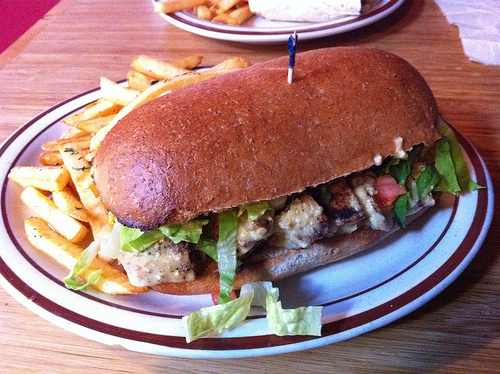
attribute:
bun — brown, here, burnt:
[92, 46, 443, 295]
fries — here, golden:
[8, 52, 249, 296]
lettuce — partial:
[180, 281, 324, 344]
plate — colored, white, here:
[0, 65, 494, 358]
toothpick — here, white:
[287, 30, 298, 84]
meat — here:
[120, 168, 397, 288]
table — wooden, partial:
[0, 0, 499, 373]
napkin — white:
[433, 1, 499, 67]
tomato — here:
[376, 175, 407, 212]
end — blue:
[287, 37, 298, 69]